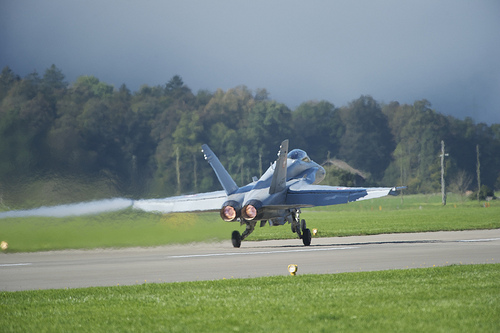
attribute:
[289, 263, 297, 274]
light — runway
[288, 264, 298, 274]
cover — yellow, metal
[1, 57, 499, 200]
tree line — dense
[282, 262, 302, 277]
light — yellow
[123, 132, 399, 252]
airplane —  silver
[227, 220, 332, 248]
landing gear —  of fighter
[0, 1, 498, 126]
sky — dark blue, blue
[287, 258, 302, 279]
object — yellow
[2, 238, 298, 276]
runway — airport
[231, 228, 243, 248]
tire — black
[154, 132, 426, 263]
jet — fighter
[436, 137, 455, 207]
pole — wooden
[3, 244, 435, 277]
runway — asphalt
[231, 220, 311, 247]
landing gear — jet , aircraft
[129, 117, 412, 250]
jet — military, fighter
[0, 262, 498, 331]
grass — green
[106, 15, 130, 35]
clouds — white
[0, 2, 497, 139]
sky — blue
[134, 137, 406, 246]
jet — gray, painted tactical, military, silver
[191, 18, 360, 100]
clouds — white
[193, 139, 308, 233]
stabilizer —  two ,   vertical 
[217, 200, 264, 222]
engines — aircraft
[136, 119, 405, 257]
plane — jet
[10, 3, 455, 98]
clouds — white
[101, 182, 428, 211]
wings —  two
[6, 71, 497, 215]
forest — dense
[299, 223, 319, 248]
right tire — black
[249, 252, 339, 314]
light — yellow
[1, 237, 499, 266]
line — white 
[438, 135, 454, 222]
wooden poles — telephone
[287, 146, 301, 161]
cockpit — fighter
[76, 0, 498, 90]
clouds — white